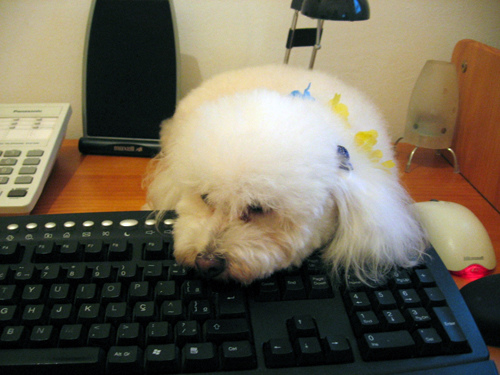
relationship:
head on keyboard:
[145, 89, 422, 282] [65, 204, 469, 368]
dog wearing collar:
[141, 61, 439, 286] [275, 86, 397, 167]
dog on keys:
[141, 61, 439, 286] [0, 214, 475, 374]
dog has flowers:
[141, 61, 427, 286] [278, 68, 422, 194]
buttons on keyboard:
[5, 237, 462, 367] [7, 193, 492, 368]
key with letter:
[129, 279, 146, 297] [134, 283, 143, 290]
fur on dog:
[152, 51, 439, 298] [126, 81, 410, 258]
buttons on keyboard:
[60, 273, 233, 340] [4, 224, 480, 369]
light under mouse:
[465, 263, 485, 277] [410, 199, 495, 269]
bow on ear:
[319, 140, 376, 175] [326, 162, 400, 276]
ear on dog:
[326, 162, 400, 276] [141, 61, 439, 286]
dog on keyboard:
[141, 61, 439, 286] [7, 193, 492, 368]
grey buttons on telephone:
[1, 147, 46, 187] [3, 97, 80, 222]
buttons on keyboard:
[2, 211, 167, 260] [33, 195, 473, 365]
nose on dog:
[188, 248, 231, 277] [141, 61, 439, 286]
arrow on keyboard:
[294, 312, 304, 327] [6, 218, 174, 367]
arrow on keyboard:
[329, 338, 341, 347] [6, 218, 174, 367]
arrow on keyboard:
[299, 340, 314, 348] [6, 218, 174, 367]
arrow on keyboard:
[271, 340, 283, 351] [6, 218, 174, 367]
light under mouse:
[465, 263, 485, 274] [408, 197, 496, 277]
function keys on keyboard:
[2, 215, 183, 236] [0, 203, 498, 372]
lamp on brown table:
[283, 1, 371, 88] [34, 136, 499, 373]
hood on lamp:
[299, 0, 371, 23] [283, 1, 371, 88]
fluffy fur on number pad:
[327, 178, 422, 260] [334, 232, 437, 282]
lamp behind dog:
[283, 1, 371, 88] [141, 61, 439, 286]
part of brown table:
[86, 175, 117, 195] [34, 136, 499, 373]